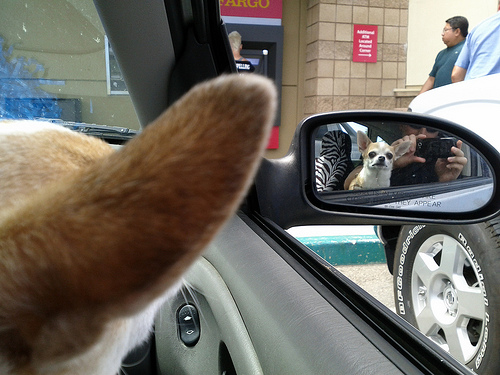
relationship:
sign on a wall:
[357, 27, 380, 65] [317, 2, 409, 109]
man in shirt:
[414, 15, 467, 94] [429, 43, 467, 88]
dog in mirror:
[346, 130, 409, 193] [311, 116, 496, 218]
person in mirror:
[343, 118, 469, 193] [311, 116, 496, 218]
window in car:
[190, 42, 493, 362] [16, 42, 489, 373]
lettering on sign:
[354, 25, 375, 56] [349, 22, 381, 64]